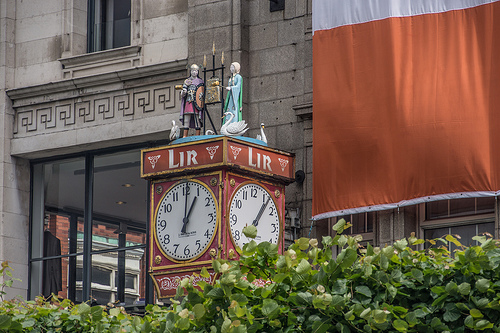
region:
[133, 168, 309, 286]
Clocks on a tower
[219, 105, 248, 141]
swam on a clock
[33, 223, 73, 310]
jacket in the window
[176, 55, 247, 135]
Statue on a clock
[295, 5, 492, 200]
flag on a building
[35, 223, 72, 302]
black jacket hanging on the wall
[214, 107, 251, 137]
A swan sculpture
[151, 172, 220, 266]
Clock face showing 1 o'clock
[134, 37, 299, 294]
An old fashioned glockenspiel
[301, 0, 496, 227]
Orange from the Irish Tricolor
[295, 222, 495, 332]
Green leaves in front of window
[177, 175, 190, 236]
Minute hand at twelve on a clock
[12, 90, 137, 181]
An ornate design over doorway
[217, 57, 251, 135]
Princess in front of swan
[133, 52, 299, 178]
Children of Lir from the Irish legend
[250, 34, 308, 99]
Brickwork from Irish building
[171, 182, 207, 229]
black hands on clock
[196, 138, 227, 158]
diamond design on clock base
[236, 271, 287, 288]
buds on green bush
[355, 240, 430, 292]
green leaves on bushes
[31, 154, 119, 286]
black frame on store's window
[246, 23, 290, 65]
large gray bricks on wall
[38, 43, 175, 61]
small gray ledge on window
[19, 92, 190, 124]
design on front of store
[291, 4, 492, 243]
orange and white banner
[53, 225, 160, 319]
reflection in the glass front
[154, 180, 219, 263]
a clock displaying 1:00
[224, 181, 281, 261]
a white faced clock displaying 1:07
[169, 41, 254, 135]
a religious statue on top of the clock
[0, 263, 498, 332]
a green hedge in front of the clock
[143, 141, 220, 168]
an advertisement name or brand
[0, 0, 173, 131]
a grey commercial building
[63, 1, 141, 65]
a window above the entrance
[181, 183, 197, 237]
the clock hands are black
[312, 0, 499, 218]
an orange and white canopy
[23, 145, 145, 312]
a large bronze window frame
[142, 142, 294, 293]
pair of clocks on a short tower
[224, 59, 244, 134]
statue of a woman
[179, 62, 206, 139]
statue of a knight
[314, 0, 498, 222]
big white and red flag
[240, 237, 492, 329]
the top of bushes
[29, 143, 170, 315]
tall glass doorway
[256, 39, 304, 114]
oversized stone bricks on a building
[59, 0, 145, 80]
window with an outside sill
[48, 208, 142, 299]
brick building with a white window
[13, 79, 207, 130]
square designs over the doorway